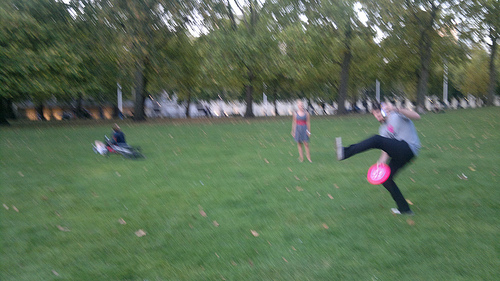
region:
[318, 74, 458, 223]
he is playing with a frisbee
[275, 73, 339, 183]
she is wearing a dress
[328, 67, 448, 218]
he is catching the frisbee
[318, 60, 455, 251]
he is throwing the disc under his leg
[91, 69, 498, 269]
they are on a grass field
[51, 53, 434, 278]
they are in a park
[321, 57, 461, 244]
his shirt is grey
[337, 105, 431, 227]
A man is plating frisbee.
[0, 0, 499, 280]
The entire imageis blurry.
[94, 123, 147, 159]
Someone is riding a trike.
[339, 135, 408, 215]
A frisbee is between two legs.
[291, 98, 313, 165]
A woman is standing on grass.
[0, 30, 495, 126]
Trees are at the edge of a field.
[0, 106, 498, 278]
The grass is green.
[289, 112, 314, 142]
A woman is wearing a blue top and skirt with a pink middle.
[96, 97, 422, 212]
Three people are on green grass.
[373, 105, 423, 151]
man wearing a gray shirt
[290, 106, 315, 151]
man wearing a blue dress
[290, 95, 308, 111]
woman with blond hair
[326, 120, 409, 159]
man with his leg up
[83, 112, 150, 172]
person sitting in the grass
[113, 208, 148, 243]
leaves on the grass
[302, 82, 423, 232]
man playing with frisbee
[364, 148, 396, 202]
the frisbee is pink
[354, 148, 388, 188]
the frisbee is pink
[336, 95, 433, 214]
Man in gray shirt holding frisbee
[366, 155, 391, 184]
Red frisbee in man's hand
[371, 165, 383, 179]
White design on top of frisbee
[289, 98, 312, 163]
Woman in gray dress standing in field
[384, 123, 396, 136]
Red and gray design on man's shirt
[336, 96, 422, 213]
Man holding frisbee between legs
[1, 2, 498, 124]
Group of trees in the background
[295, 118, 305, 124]
Red belt around woman's waist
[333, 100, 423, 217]
Man with frisbee in hand posing for picture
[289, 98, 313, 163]
Woman in field next to man with frisbee